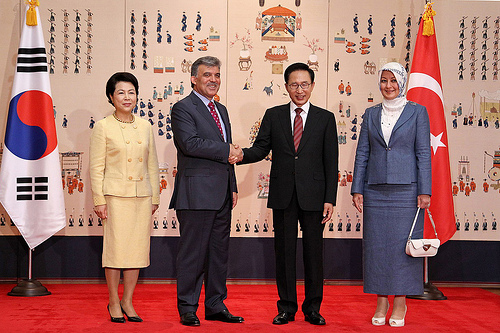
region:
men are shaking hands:
[170, 30, 354, 188]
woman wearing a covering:
[360, 44, 407, 105]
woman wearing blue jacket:
[347, 96, 442, 199]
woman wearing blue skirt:
[355, 176, 427, 293]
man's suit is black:
[250, 99, 350, 327]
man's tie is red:
[286, 103, 312, 153]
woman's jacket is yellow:
[87, 111, 167, 205]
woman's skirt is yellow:
[93, 191, 155, 280]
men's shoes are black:
[179, 294, 331, 330]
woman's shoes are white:
[352, 296, 423, 331]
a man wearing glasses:
[263, 52, 324, 169]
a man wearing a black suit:
[257, 42, 327, 242]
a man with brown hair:
[247, 35, 332, 277]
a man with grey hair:
[162, 50, 248, 174]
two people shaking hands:
[169, 42, 341, 236]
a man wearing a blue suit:
[160, 52, 272, 280]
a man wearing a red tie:
[183, 63, 240, 170]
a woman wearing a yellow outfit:
[65, 51, 182, 310]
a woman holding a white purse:
[351, 62, 449, 282]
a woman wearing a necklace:
[93, 72, 178, 199]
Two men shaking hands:
[176, 60, 342, 324]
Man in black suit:
[239, 62, 339, 331]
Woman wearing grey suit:
[352, 62, 445, 331]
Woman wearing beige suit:
[90, 70, 167, 323]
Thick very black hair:
[106, 71, 142, 93]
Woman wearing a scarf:
[374, 62, 416, 110]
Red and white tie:
[210, 99, 230, 135]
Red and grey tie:
[293, 107, 305, 148]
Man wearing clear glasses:
[284, 62, 318, 108]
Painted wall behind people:
[57, 5, 499, 142]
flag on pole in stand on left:
[1, 1, 68, 298]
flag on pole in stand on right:
[399, 1, 461, 303]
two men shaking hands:
[165, 49, 340, 331]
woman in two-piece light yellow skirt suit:
[85, 66, 164, 328]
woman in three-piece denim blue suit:
[350, 56, 443, 331]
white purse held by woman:
[402, 198, 442, 262]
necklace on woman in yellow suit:
[111, 106, 134, 122]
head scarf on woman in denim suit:
[375, 57, 410, 102]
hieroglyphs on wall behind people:
[4, 1, 497, 236]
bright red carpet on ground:
[5, 276, 499, 332]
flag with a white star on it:
[403, 2, 480, 310]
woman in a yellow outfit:
[66, 58, 168, 330]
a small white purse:
[388, 190, 452, 277]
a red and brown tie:
[276, 102, 321, 155]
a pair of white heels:
[330, 294, 423, 331]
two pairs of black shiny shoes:
[186, 300, 324, 325]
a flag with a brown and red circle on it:
[1, 35, 68, 305]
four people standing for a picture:
[86, 39, 415, 331]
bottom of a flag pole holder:
[3, 233, 60, 331]